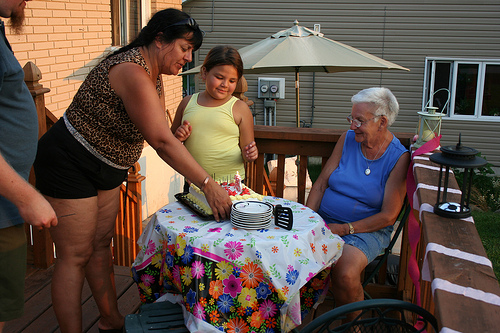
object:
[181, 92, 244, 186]
shirt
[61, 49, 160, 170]
shirt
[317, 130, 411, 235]
shirt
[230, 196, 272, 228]
plate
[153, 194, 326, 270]
table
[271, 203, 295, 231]
spatulla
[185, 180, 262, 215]
cake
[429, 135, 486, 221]
lantern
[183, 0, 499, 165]
building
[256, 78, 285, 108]
meter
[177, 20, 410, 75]
umbrella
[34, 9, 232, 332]
woman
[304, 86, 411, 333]
woman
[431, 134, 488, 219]
candle holder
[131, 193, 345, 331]
cloth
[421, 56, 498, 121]
window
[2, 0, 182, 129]
house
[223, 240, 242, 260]
flower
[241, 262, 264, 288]
flower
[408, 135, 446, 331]
streamer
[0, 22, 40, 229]
shirt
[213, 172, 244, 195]
birthday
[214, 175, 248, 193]
candles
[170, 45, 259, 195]
girl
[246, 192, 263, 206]
slices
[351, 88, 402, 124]
hair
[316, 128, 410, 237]
blue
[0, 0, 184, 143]
wall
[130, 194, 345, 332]
tablecloth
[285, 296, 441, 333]
chair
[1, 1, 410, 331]
people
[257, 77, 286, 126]
utility box